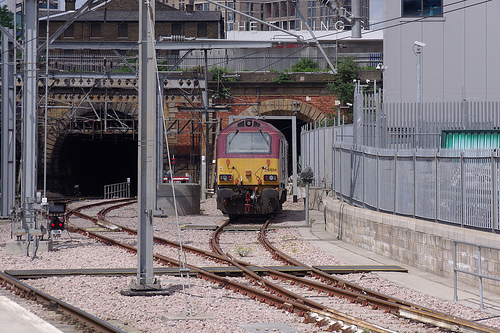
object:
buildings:
[0, 0, 500, 244]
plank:
[3, 266, 409, 279]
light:
[264, 174, 277, 181]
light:
[219, 174, 232, 181]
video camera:
[414, 40, 427, 47]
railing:
[35, 52, 336, 72]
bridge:
[0, 73, 380, 200]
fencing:
[299, 79, 500, 237]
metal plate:
[215, 185, 282, 218]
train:
[215, 118, 289, 225]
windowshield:
[226, 131, 272, 155]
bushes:
[0, 48, 383, 127]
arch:
[234, 98, 333, 128]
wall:
[0, 0, 500, 321]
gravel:
[0, 195, 500, 333]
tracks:
[255, 211, 499, 333]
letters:
[237, 20, 364, 31]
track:
[0, 267, 145, 333]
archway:
[46, 108, 139, 197]